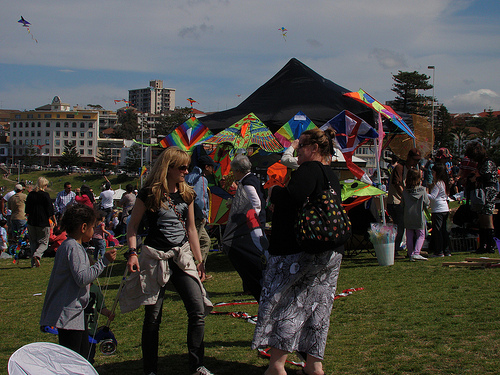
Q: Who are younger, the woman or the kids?
A: The kids are younger than the woman.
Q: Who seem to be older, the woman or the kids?
A: The woman are older than the kids.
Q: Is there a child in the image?
A: Yes, there are children.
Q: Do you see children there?
A: Yes, there are children.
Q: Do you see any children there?
A: Yes, there are children.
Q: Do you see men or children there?
A: Yes, there are children.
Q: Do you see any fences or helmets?
A: No, there are no fences or helmets.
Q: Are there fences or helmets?
A: No, there are no fences or helmets.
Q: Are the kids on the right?
A: Yes, the kids are on the right of the image.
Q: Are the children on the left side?
A: No, the children are on the right of the image.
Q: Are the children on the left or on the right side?
A: The children are on the right of the image.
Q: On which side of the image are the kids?
A: The kids are on the right of the image.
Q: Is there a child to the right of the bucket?
A: Yes, there are children to the right of the bucket.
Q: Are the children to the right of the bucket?
A: Yes, the children are to the right of the bucket.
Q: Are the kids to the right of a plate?
A: No, the kids are to the right of the bucket.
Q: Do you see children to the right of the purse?
A: Yes, there are children to the right of the purse.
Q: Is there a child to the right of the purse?
A: Yes, there are children to the right of the purse.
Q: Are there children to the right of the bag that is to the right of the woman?
A: Yes, there are children to the right of the purse.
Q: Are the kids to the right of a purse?
A: Yes, the kids are to the right of a purse.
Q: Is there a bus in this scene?
A: No, there are no buses.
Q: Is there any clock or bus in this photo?
A: No, there are no buses or clocks.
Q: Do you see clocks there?
A: No, there are no clocks.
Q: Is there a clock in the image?
A: No, there are no clocks.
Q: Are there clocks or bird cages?
A: No, there are no clocks or bird cages.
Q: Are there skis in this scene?
A: No, there are no skis.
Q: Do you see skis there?
A: No, there are no skis.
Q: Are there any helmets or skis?
A: No, there are no skis or helmets.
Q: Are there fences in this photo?
A: No, there are no fences.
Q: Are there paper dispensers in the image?
A: No, there are no paper dispensers.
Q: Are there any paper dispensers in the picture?
A: No, there are no paper dispensers.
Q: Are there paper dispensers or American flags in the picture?
A: No, there are no paper dispensers or American flags.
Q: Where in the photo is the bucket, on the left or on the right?
A: The bucket is on the right of the image.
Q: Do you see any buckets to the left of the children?
A: Yes, there is a bucket to the left of the children.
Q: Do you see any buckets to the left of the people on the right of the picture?
A: Yes, there is a bucket to the left of the children.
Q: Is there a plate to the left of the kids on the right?
A: No, there is a bucket to the left of the kids.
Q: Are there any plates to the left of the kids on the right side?
A: No, there is a bucket to the left of the kids.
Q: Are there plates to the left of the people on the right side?
A: No, there is a bucket to the left of the kids.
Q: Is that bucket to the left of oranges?
A: No, the bucket is to the left of the children.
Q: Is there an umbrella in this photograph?
A: No, there are no umbrellas.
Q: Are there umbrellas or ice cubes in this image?
A: No, there are no umbrellas or ice cubes.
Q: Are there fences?
A: No, there are no fences.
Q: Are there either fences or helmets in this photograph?
A: No, there are no fences or helmets.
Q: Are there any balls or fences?
A: No, there are no fences or balls.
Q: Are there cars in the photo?
A: No, there are no cars.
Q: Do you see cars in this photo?
A: No, there are no cars.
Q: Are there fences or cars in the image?
A: No, there are no cars or fences.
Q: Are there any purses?
A: Yes, there is a purse.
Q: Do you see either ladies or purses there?
A: Yes, there is a purse.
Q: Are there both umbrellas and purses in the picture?
A: No, there is a purse but no umbrellas.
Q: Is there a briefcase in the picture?
A: No, there are no briefcases.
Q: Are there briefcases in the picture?
A: No, there are no briefcases.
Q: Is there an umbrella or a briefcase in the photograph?
A: No, there are no briefcases or umbrellas.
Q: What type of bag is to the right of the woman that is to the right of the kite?
A: The bag is a purse.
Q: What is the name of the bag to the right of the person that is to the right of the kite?
A: The bag is a purse.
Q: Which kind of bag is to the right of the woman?
A: The bag is a purse.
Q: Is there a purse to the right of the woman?
A: Yes, there is a purse to the right of the woman.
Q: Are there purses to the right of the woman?
A: Yes, there is a purse to the right of the woman.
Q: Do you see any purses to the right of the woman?
A: Yes, there is a purse to the right of the woman.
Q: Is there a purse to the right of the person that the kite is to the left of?
A: Yes, there is a purse to the right of the woman.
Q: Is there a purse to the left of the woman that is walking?
A: No, the purse is to the right of the woman.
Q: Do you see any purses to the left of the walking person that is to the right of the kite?
A: No, the purse is to the right of the woman.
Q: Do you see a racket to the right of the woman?
A: No, there is a purse to the right of the woman.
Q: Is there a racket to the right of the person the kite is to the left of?
A: No, there is a purse to the right of the woman.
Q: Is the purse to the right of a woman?
A: Yes, the purse is to the right of a woman.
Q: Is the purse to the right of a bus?
A: No, the purse is to the right of a woman.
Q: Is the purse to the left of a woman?
A: No, the purse is to the right of a woman.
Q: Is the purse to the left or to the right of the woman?
A: The purse is to the right of the woman.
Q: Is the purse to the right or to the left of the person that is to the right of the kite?
A: The purse is to the right of the woman.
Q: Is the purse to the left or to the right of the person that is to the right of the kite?
A: The purse is to the right of the woman.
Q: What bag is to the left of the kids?
A: The bag is a purse.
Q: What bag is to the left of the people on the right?
A: The bag is a purse.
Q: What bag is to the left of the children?
A: The bag is a purse.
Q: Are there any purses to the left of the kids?
A: Yes, there is a purse to the left of the kids.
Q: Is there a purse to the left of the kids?
A: Yes, there is a purse to the left of the kids.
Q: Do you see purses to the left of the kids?
A: Yes, there is a purse to the left of the kids.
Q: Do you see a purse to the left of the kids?
A: Yes, there is a purse to the left of the kids.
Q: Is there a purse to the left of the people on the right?
A: Yes, there is a purse to the left of the kids.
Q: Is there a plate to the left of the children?
A: No, there is a purse to the left of the children.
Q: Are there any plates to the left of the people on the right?
A: No, there is a purse to the left of the children.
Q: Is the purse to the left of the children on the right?
A: Yes, the purse is to the left of the kids.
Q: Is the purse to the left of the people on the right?
A: Yes, the purse is to the left of the kids.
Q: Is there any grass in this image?
A: Yes, there is grass.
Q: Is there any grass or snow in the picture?
A: Yes, there is grass.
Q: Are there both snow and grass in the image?
A: No, there is grass but no snow.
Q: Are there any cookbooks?
A: No, there are no cookbooks.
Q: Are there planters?
A: No, there are no planters.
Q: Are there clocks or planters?
A: No, there are no planters or clocks.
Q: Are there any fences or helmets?
A: No, there are no fences or helmets.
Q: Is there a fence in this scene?
A: No, there are no fences.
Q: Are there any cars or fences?
A: No, there are no fences or cars.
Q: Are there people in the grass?
A: Yes, there are people in the grass.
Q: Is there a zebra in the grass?
A: No, there are people in the grass.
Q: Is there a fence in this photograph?
A: No, there are no fences.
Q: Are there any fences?
A: No, there are no fences.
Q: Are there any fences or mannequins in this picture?
A: No, there are no fences or mannequins.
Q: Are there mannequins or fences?
A: No, there are no fences or mannequins.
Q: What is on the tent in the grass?
A: The kites are on the tent.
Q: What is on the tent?
A: The kites are on the tent.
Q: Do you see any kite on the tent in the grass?
A: Yes, there are kites on the tent.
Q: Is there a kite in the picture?
A: Yes, there is a kite.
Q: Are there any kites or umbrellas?
A: Yes, there is a kite.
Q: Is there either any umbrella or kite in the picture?
A: Yes, there is a kite.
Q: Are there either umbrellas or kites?
A: Yes, there is a kite.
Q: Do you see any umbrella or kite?
A: Yes, there is a kite.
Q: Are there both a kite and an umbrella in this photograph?
A: No, there is a kite but no umbrellas.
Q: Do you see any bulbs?
A: No, there are no bulbs.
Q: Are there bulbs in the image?
A: No, there are no bulbs.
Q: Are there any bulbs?
A: No, there are no bulbs.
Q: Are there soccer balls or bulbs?
A: No, there are no bulbs or soccer balls.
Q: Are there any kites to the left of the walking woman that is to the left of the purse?
A: Yes, there is a kite to the left of the woman.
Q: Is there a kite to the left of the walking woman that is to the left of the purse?
A: Yes, there is a kite to the left of the woman.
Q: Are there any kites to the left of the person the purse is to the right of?
A: Yes, there is a kite to the left of the woman.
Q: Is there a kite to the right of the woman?
A: No, the kite is to the left of the woman.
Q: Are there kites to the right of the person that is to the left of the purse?
A: No, the kite is to the left of the woman.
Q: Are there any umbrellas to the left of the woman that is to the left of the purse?
A: No, there is a kite to the left of the woman.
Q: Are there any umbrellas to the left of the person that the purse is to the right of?
A: No, there is a kite to the left of the woman.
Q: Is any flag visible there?
A: No, there are no flags.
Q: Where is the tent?
A: The tent is in the grass.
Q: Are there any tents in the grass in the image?
A: Yes, there is a tent in the grass.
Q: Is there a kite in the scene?
A: Yes, there is a kite.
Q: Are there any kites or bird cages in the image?
A: Yes, there is a kite.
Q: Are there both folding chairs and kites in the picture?
A: No, there is a kite but no folding chairs.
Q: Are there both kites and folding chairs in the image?
A: No, there is a kite but no folding chairs.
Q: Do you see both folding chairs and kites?
A: No, there is a kite but no folding chairs.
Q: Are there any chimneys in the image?
A: No, there are no chimneys.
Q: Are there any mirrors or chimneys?
A: No, there are no chimneys or mirrors.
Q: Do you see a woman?
A: Yes, there is a woman.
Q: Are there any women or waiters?
A: Yes, there is a woman.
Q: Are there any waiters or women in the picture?
A: Yes, there is a woman.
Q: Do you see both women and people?
A: Yes, there are both a woman and a person.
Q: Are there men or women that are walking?
A: Yes, the woman is walking.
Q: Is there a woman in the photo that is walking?
A: Yes, there is a woman that is walking.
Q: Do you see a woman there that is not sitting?
A: Yes, there is a woman that is walking .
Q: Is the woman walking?
A: Yes, the woman is walking.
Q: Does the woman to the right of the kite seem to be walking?
A: Yes, the woman is walking.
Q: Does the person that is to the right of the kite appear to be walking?
A: Yes, the woman is walking.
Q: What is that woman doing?
A: The woman is walking.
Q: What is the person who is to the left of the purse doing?
A: The woman is walking.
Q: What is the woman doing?
A: The woman is walking.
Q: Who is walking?
A: The woman is walking.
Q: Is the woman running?
A: No, the woman is walking.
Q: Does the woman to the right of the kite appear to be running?
A: No, the woman is walking.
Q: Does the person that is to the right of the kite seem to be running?
A: No, the woman is walking.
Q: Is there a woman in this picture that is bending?
A: No, there is a woman but she is walking.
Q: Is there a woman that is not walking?
A: No, there is a woman but she is walking.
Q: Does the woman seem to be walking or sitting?
A: The woman is walking.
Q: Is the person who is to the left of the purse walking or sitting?
A: The woman is walking.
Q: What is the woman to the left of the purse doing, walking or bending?
A: The woman is walking.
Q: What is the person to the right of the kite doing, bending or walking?
A: The woman is walking.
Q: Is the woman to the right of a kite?
A: Yes, the woman is to the right of a kite.